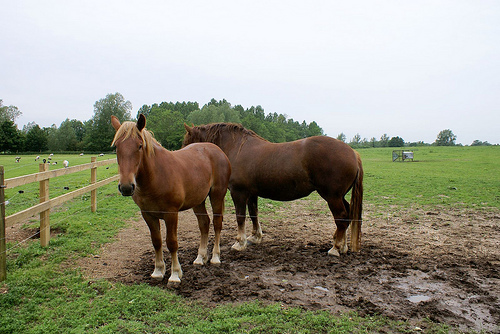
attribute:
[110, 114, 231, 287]
horse — brown, front right, standing, fat, short, staring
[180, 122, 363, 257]
horse — brown, dark colored, standing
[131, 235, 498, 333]
mud — muddy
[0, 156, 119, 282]
fence — brown, wooden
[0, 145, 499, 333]
field — muddy, green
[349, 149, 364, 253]
tail — long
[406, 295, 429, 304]
puddle — of water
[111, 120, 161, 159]
mane — blonde, gold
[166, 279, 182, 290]
hoof — front right, brown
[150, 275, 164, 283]
hoof — brown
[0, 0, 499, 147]
sky — cloudy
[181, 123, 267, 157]
hair — brown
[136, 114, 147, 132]
ear — large, pointy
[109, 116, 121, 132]
ear — large, pointy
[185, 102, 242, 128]
tree — green, background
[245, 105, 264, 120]
tree — green, background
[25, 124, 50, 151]
tree — green, background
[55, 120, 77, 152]
tree — green, background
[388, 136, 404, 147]
tree — green, background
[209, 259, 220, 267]
hoof — brown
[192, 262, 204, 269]
hoof — brown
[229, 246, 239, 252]
hoof — brown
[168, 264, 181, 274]
fetlock — white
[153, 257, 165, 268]
fetlock — white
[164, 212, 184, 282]
leg — white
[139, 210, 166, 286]
leg — white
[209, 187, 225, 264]
leg — white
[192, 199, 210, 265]
leg — white